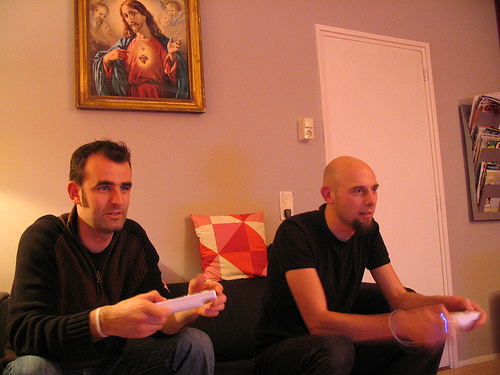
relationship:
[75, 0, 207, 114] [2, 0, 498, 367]
picture of jesus on wall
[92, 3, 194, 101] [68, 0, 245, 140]
jesus in picture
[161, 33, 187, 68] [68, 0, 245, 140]
hand in picture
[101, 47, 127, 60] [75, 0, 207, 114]
hand in picture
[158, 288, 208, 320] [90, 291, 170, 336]
wii controller in hand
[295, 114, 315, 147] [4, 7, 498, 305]
thermostat on wall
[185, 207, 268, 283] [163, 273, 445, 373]
pillow on couch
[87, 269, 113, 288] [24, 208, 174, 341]
zipper on sweater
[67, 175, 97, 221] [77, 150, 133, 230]
side burn on face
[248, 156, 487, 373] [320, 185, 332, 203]
man has right ear